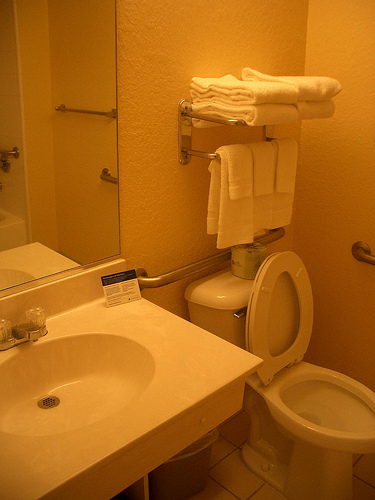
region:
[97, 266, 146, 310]
Sign on a sink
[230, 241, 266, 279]
Toilet paper roll on tank of toilet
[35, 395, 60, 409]
Water drain in the sink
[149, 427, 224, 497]
Garbage can under a sink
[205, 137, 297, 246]
Towels draped over a handle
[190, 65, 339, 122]
White towels stacked on a shelf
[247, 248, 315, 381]
Toilet seat and lid up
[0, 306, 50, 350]
Water tap on a sink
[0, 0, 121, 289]
Mirror over a sink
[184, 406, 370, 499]
tile on a bathroom floor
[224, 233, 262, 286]
a roll of toilet paper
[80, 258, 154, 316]
a sign on bath sink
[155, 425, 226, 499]
a tan trash can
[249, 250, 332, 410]
a raised toilet seat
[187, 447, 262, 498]
a tiled bath floor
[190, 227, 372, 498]
a clean white toilet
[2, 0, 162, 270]
a large mirror on wall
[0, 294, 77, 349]
a silver bathroom sink fauset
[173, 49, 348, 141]
a stack of towels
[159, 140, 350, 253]
white towels hanging on bar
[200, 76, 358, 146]
the towels are folded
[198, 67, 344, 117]
the towels are white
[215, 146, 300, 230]
the towels are hanged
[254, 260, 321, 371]
the toilet seat is up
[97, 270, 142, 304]
card is on the sink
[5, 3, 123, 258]
reflection is in the mirror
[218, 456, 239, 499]
the floor is tiled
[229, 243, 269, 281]
toilet paper is on the toilet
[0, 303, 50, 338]
the knobs rae clearin color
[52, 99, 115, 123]
handle is on the wall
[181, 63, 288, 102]
white towel folded on rack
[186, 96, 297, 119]
white towel folded on rack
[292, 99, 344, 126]
white towel folded on rack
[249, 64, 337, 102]
white towel folded on rack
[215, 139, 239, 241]
white towel hanging on rack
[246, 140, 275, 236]
white towel hanging on rack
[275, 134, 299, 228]
white towel hanging on rack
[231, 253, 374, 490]
white toilet on right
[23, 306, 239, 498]
white sink on left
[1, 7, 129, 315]
bathroom mirror on left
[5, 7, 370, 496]
a bathroom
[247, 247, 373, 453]
the toilet seat is up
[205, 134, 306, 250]
towels hanging above the toilet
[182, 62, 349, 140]
towels stacked on a rack above the toilet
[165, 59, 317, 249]
a towel rack on the wall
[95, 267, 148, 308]
a plastic sign on the sink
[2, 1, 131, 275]
a mirror attached to the wall above the sink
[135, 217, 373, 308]
metal safety rails around the toilet on the walls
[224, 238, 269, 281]
an extra roll of toilet paper on the toilet tank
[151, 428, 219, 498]
a trash can with a liner